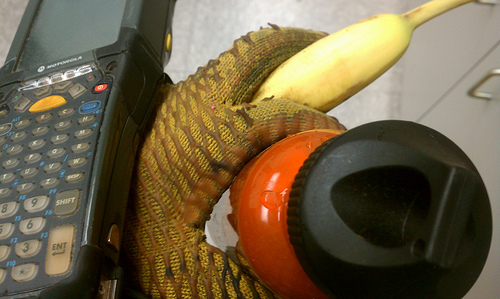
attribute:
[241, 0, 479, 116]
banana — yellow, ripe, brownish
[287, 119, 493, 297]
lid — black, plastic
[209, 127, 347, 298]
cup — orange, oblong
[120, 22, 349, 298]
cover — tan, yellow, brown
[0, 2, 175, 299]
scanner — black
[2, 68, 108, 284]
buttons — grey, many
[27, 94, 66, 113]
button — yellow, orange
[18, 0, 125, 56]
screen — blank, on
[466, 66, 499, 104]
handle — silver, shiny, steel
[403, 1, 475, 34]
stalk — yellow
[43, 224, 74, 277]
button — white, dirty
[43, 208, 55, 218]
numbers — blue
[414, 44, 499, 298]
door — white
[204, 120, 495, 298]
container — plastic, red, black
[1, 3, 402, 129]
floor — under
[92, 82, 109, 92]
button — red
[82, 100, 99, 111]
button — blue